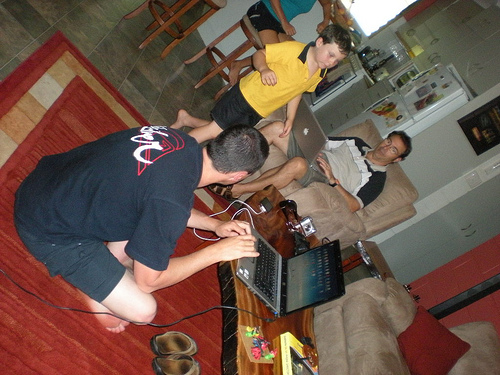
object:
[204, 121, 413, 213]
dad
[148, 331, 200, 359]
shoes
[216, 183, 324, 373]
coffee table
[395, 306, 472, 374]
pillow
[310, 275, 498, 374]
couch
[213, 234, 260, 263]
hand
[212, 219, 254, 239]
hand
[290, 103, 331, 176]
computer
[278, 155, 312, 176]
lap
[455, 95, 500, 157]
frame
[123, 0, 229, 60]
wood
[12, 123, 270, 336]
guy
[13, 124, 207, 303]
black shirt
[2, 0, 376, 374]
floor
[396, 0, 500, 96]
cabinet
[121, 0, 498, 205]
kitchen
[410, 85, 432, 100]
magnets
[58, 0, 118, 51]
tile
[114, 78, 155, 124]
tile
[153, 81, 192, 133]
tile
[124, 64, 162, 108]
tile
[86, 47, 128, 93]
tile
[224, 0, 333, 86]
mom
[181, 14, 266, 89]
bar stool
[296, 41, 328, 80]
collar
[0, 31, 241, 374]
carpet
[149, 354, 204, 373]
slippers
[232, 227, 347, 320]
laptop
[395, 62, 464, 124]
doors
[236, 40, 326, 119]
shirt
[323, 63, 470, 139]
refrigerator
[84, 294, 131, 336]
foot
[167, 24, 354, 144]
son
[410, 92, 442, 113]
stuff